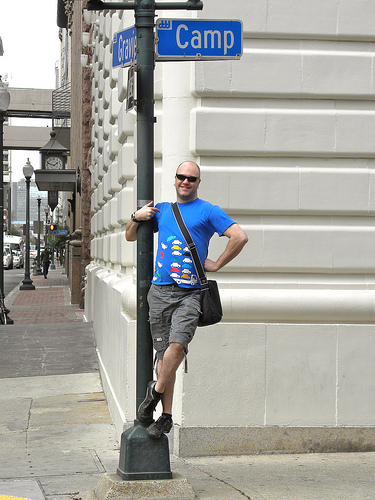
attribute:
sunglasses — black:
[171, 164, 209, 189]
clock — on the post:
[34, 139, 66, 171]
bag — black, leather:
[198, 271, 260, 321]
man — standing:
[99, 149, 262, 438]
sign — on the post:
[152, 16, 243, 58]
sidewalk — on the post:
[5, 257, 372, 499]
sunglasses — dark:
[175, 173, 196, 178]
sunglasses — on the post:
[171, 168, 205, 184]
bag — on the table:
[193, 268, 232, 332]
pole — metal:
[133, 0, 157, 416]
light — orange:
[48, 223, 55, 232]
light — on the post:
[15, 153, 52, 299]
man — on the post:
[125, 162, 247, 443]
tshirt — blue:
[143, 199, 237, 288]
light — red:
[46, 221, 66, 227]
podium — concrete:
[88, 470, 198, 498]